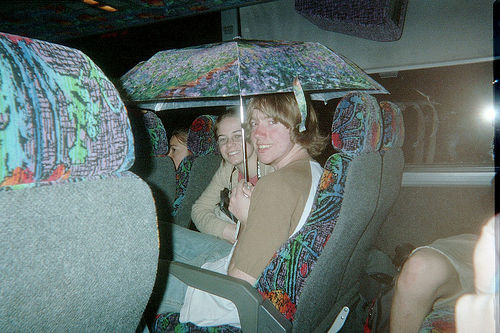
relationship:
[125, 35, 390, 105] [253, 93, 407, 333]
umbrella matches gray/colorful seats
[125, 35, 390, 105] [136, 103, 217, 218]
umbrella matches seats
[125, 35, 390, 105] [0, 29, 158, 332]
umbrella matches back seat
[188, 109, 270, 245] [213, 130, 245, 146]
girl wearing glasses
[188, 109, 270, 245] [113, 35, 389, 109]
girl holding umbrella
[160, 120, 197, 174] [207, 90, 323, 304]
head sitting in front of couple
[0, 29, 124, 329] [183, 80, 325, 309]
back seat across from couple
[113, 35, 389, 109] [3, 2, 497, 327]
umbrella inside bus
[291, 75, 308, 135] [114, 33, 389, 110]
strap hanging from umbrella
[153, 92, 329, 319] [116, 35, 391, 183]
boy under umbrella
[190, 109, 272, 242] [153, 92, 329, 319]
girl under boy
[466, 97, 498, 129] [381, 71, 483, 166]
light on window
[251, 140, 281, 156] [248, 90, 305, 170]
smile on face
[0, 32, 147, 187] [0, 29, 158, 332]
headrest on back seat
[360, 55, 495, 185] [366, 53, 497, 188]
window on bus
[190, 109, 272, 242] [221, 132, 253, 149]
girl wears glasses